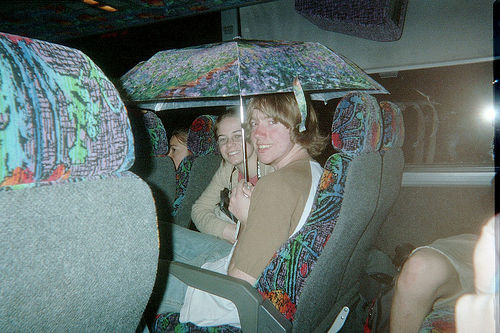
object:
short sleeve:
[179, 157, 324, 327]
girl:
[190, 109, 272, 242]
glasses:
[218, 132, 251, 144]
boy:
[153, 92, 329, 319]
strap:
[291, 75, 309, 134]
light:
[476, 104, 496, 124]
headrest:
[0, 32, 147, 187]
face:
[248, 90, 296, 165]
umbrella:
[113, 35, 389, 109]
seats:
[124, 108, 177, 218]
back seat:
[0, 29, 158, 332]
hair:
[248, 93, 331, 159]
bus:
[3, 2, 499, 331]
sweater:
[191, 163, 273, 239]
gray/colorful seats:
[253, 93, 407, 333]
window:
[370, 60, 492, 169]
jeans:
[140, 223, 232, 324]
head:
[167, 130, 195, 171]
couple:
[155, 94, 328, 316]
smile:
[254, 143, 270, 154]